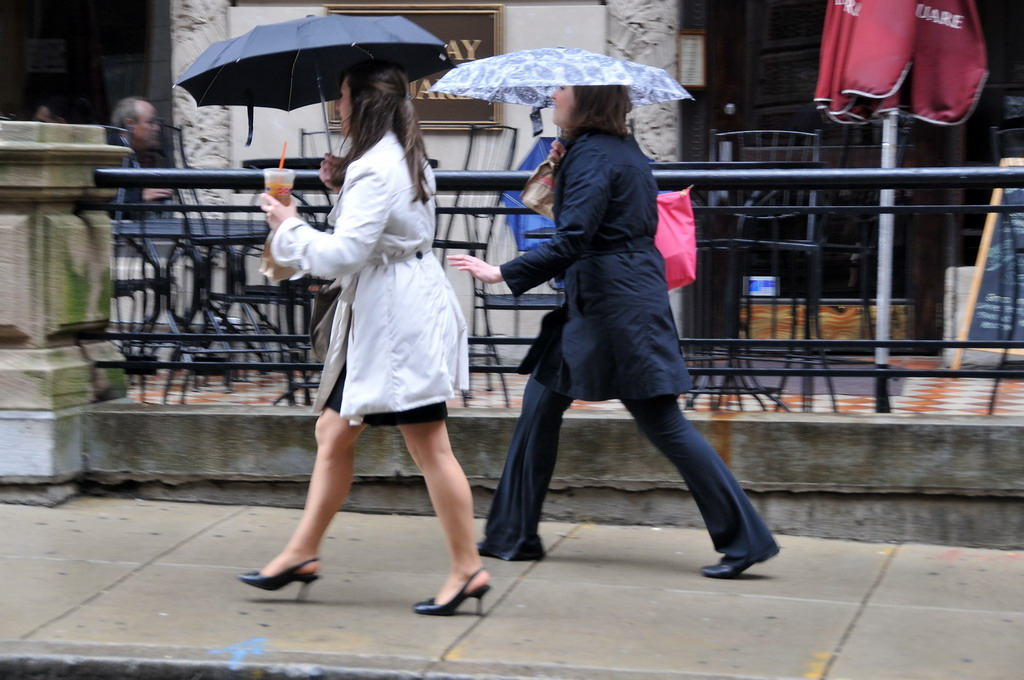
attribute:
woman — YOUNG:
[306, 73, 451, 653]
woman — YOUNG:
[492, 103, 709, 531]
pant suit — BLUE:
[486, 120, 716, 594]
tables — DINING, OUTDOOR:
[114, 127, 1011, 231]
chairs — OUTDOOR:
[92, 188, 939, 353]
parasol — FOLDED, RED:
[814, 10, 970, 117]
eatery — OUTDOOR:
[40, 12, 1021, 665]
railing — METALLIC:
[94, 153, 1013, 212]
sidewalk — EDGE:
[49, 360, 1013, 667]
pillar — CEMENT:
[157, 4, 278, 326]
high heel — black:
[226, 541, 348, 613]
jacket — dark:
[503, 115, 724, 414]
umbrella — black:
[166, 9, 458, 105]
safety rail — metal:
[119, 171, 253, 405]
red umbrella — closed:
[786, 13, 990, 413]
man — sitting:
[86, 83, 205, 263]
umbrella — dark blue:
[157, 9, 447, 120]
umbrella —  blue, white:
[414, 31, 715, 114]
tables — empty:
[48, 172, 1019, 432]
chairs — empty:
[63, 98, 1019, 427]